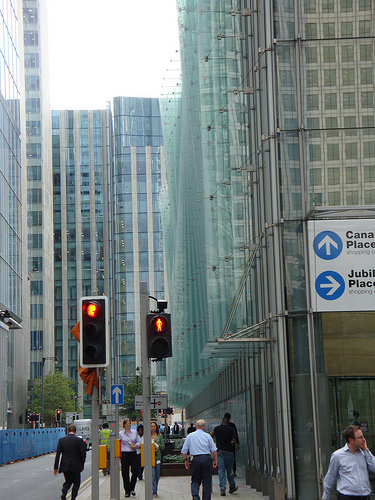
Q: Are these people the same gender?
A: No, they are both male and female.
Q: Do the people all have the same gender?
A: No, they are both male and female.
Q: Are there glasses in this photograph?
A: No, there are no glasses.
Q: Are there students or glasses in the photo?
A: No, there are no glasses or students.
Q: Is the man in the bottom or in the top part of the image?
A: The man is in the bottom of the image.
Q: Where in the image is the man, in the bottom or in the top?
A: The man is in the bottom of the image.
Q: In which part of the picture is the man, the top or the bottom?
A: The man is in the bottom of the image.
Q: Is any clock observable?
A: No, there are no clocks.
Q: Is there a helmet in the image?
A: No, there are no helmets.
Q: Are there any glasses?
A: No, there are no glasses.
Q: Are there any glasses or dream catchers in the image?
A: No, there are no glasses or dream catchers.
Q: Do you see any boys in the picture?
A: No, there are no boys.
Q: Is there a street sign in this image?
A: Yes, there is a street sign.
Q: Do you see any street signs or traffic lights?
A: Yes, there is a street sign.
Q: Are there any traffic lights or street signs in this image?
A: Yes, there is a street sign.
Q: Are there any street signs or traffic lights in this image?
A: Yes, there is a street sign.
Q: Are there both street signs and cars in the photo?
A: No, there is a street sign but no cars.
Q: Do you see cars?
A: No, there are no cars.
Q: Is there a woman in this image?
A: Yes, there is a woman.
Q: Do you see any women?
A: Yes, there is a woman.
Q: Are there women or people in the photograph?
A: Yes, there is a woman.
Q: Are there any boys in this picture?
A: No, there are no boys.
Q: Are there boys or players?
A: No, there are no boys or players.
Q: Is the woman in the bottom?
A: Yes, the woman is in the bottom of the image.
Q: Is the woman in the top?
A: No, the woman is in the bottom of the image.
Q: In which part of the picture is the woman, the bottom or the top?
A: The woman is in the bottom of the image.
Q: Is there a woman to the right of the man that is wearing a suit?
A: Yes, there is a woman to the right of the man.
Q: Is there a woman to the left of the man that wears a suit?
A: No, the woman is to the right of the man.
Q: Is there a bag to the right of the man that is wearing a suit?
A: No, there is a woman to the right of the man.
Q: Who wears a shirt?
A: The woman wears a shirt.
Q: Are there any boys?
A: No, there are no boys.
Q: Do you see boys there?
A: No, there are no boys.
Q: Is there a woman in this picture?
A: Yes, there is a woman.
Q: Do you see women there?
A: Yes, there is a woman.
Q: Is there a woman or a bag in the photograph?
A: Yes, there is a woman.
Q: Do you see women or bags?
A: Yes, there is a woman.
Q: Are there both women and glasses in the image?
A: No, there is a woman but no glasses.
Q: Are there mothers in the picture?
A: No, there are no mothers.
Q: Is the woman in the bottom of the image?
A: Yes, the woman is in the bottom of the image.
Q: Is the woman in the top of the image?
A: No, the woman is in the bottom of the image.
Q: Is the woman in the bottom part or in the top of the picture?
A: The woman is in the bottom of the image.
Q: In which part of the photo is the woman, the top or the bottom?
A: The woman is in the bottom of the image.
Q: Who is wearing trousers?
A: The woman is wearing trousers.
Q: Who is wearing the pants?
A: The woman is wearing trousers.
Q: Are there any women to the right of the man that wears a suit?
A: Yes, there is a woman to the right of the man.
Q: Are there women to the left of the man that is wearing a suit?
A: No, the woman is to the right of the man.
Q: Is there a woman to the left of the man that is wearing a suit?
A: No, the woman is to the right of the man.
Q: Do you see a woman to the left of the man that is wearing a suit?
A: No, the woman is to the right of the man.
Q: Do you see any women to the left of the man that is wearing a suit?
A: No, the woman is to the right of the man.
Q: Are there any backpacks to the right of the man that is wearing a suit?
A: No, there is a woman to the right of the man.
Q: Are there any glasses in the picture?
A: No, there are no glasses.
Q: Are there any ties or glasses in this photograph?
A: No, there are no glasses or ties.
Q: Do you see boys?
A: No, there are no boys.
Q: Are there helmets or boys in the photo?
A: No, there are no boys or helmets.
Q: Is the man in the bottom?
A: Yes, the man is in the bottom of the image.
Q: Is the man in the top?
A: No, the man is in the bottom of the image.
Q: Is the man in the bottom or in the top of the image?
A: The man is in the bottom of the image.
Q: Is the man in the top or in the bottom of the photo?
A: The man is in the bottom of the image.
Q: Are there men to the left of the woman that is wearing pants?
A: Yes, there is a man to the left of the woman.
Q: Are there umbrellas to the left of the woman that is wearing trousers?
A: No, there is a man to the left of the woman.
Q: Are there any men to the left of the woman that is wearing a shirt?
A: Yes, there is a man to the left of the woman.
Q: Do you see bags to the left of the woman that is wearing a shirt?
A: No, there is a man to the left of the woman.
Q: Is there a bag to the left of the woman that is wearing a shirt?
A: No, there is a man to the left of the woman.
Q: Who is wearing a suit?
A: The man is wearing a suit.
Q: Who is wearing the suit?
A: The man is wearing a suit.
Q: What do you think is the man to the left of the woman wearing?
A: The man is wearing a suit.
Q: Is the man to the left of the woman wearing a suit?
A: Yes, the man is wearing a suit.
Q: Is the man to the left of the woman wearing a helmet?
A: No, the man is wearing a suit.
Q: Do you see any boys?
A: No, there are no boys.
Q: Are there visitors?
A: No, there are no visitors.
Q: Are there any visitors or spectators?
A: No, there are no visitors or spectators.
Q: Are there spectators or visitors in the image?
A: No, there are no visitors or spectators.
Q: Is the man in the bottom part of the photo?
A: Yes, the man is in the bottom of the image.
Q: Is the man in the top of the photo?
A: No, the man is in the bottom of the image.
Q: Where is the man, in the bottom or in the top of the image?
A: The man is in the bottom of the image.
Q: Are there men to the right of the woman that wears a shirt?
A: Yes, there is a man to the right of the woman.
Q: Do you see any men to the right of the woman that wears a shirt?
A: Yes, there is a man to the right of the woman.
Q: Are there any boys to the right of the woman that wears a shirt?
A: No, there is a man to the right of the woman.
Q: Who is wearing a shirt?
A: The man is wearing a shirt.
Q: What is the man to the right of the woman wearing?
A: The man is wearing a shirt.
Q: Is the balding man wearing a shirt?
A: Yes, the man is wearing a shirt.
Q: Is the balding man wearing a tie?
A: No, the man is wearing a shirt.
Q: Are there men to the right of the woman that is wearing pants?
A: Yes, there is a man to the right of the woman.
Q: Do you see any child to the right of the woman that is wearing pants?
A: No, there is a man to the right of the woman.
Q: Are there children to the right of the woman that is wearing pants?
A: No, there is a man to the right of the woman.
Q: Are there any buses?
A: No, there are no buses.